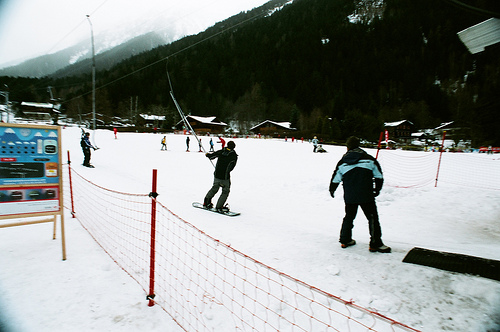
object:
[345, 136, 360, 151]
head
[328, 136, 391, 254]
man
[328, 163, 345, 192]
arm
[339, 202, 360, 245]
leg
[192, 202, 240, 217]
snowboard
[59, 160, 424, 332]
fence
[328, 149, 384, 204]
coat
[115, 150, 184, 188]
snow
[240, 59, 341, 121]
trees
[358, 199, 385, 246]
leg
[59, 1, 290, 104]
wires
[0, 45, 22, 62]
air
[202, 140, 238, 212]
people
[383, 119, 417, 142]
buildings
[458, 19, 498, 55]
back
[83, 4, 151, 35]
sky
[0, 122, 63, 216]
sign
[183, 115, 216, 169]
poles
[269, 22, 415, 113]
mountain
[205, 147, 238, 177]
top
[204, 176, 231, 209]
pants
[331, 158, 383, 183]
colors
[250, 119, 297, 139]
houses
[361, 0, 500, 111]
mountains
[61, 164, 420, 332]
net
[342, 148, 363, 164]
hood